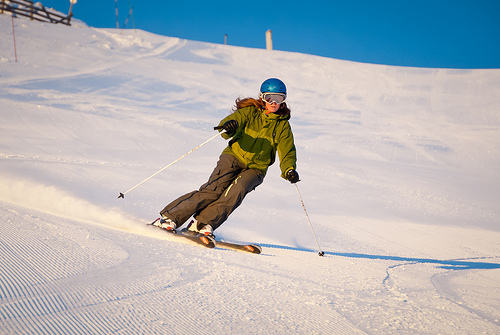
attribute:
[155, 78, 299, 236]
woman — skiing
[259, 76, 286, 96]
helmet — blue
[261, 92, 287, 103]
goggles — gray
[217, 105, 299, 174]
jacket — green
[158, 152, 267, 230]
pants — brown, black, gray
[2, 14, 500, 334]
snow — white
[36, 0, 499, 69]
sky — blue, bright blue, clear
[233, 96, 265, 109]
hair — red, long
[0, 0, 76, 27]
fence — black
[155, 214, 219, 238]
boots — white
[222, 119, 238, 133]
glove — black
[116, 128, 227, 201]
ski pole — white